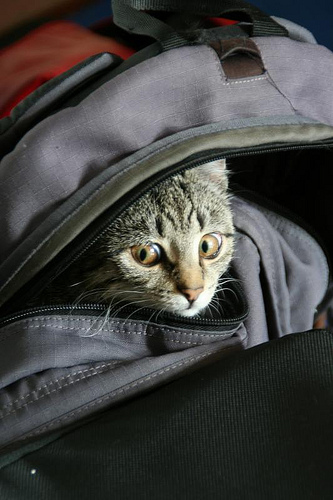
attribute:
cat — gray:
[113, 175, 225, 305]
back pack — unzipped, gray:
[40, 55, 332, 357]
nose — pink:
[179, 286, 204, 304]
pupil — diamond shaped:
[202, 237, 210, 258]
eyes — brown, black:
[124, 234, 224, 268]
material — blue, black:
[101, 76, 246, 136]